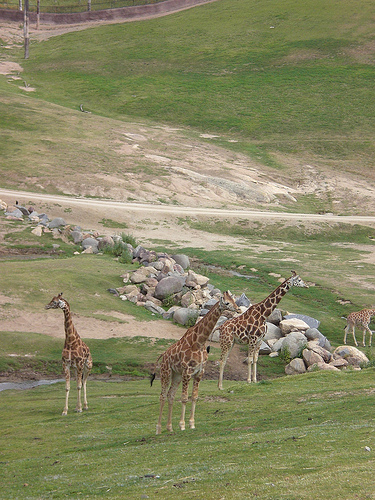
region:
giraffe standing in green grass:
[31, 279, 96, 434]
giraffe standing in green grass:
[152, 280, 222, 444]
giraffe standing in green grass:
[230, 272, 298, 398]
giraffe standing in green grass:
[338, 305, 373, 347]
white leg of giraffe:
[54, 392, 76, 417]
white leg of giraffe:
[152, 407, 165, 436]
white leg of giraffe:
[164, 411, 177, 437]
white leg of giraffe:
[174, 406, 190, 432]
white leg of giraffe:
[191, 405, 200, 431]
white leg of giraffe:
[216, 363, 233, 389]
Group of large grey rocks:
[284, 335, 329, 370]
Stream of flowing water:
[5, 380, 50, 390]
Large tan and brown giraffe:
[50, 294, 97, 421]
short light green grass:
[240, 427, 336, 477]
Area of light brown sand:
[89, 319, 167, 338]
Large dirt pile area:
[155, 149, 266, 212]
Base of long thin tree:
[22, 3, 30, 58]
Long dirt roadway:
[35, 192, 359, 223]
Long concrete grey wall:
[69, 2, 158, 18]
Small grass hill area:
[203, 11, 348, 103]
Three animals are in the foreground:
[37, 259, 307, 435]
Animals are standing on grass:
[46, 375, 261, 444]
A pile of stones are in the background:
[138, 232, 319, 362]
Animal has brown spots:
[45, 256, 310, 418]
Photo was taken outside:
[0, 10, 372, 490]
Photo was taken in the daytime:
[5, 15, 372, 495]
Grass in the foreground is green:
[2, 379, 366, 496]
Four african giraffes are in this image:
[35, 259, 369, 432]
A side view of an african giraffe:
[210, 257, 305, 394]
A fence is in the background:
[2, 0, 175, 26]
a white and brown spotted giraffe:
[45, 291, 94, 419]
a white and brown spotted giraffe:
[144, 286, 243, 439]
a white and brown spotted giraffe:
[214, 269, 310, 387]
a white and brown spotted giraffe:
[339, 305, 373, 346]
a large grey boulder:
[279, 329, 304, 361]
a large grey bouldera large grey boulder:
[154, 272, 181, 297]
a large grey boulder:
[300, 347, 322, 363]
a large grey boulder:
[328, 345, 363, 364]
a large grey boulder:
[285, 308, 319, 326]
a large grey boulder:
[278, 317, 312, 335]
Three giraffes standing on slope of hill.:
[38, 261, 325, 439]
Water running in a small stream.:
[194, 254, 275, 286]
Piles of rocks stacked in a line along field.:
[56, 216, 214, 311]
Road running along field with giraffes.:
[94, 187, 284, 227]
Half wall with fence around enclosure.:
[46, 0, 155, 26]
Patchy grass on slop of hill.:
[70, 104, 278, 192]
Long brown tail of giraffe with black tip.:
[141, 351, 167, 394]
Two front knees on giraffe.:
[176, 384, 206, 404]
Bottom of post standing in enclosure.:
[19, 5, 36, 66]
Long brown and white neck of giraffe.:
[254, 280, 301, 320]